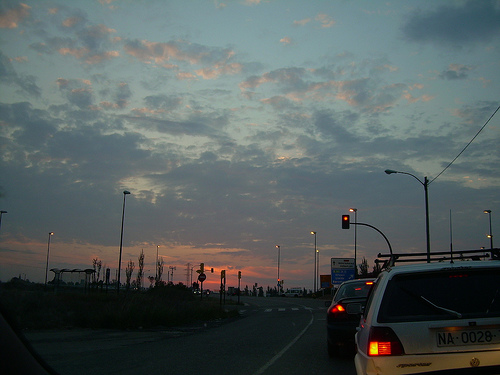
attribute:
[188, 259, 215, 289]
stoplight — red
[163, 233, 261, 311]
sunset — red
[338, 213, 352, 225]
light — red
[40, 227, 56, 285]
street light — shining, overhead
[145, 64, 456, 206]
sky — cloudy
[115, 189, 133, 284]
streetlight — tall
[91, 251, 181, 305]
trees — dark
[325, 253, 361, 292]
sign — blue, white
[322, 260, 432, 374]
lights — on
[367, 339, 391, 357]
brake light — red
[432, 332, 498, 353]
license plate — white, black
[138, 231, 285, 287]
sky — pink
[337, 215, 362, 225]
traffic light — red, signaling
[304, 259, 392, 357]
car — black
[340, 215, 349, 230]
streetlight — red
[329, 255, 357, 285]
traffic sign — blue, white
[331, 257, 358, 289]
street sign — blue